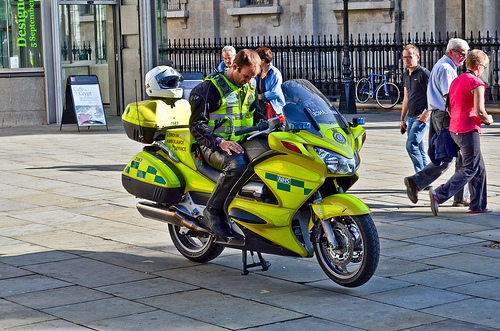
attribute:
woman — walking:
[427, 48, 495, 215]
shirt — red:
[446, 74, 487, 137]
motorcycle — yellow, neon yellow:
[121, 78, 379, 288]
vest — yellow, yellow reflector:
[202, 72, 256, 144]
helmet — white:
[144, 65, 183, 99]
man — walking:
[401, 43, 433, 191]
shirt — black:
[399, 65, 431, 118]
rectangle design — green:
[145, 164, 157, 174]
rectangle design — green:
[135, 168, 146, 178]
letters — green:
[14, 3, 39, 49]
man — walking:
[403, 36, 469, 207]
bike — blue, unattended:
[354, 64, 400, 109]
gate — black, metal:
[160, 31, 498, 103]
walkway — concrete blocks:
[1, 125, 500, 329]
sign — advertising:
[58, 74, 110, 133]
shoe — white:
[429, 188, 440, 215]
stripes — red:
[433, 192, 439, 203]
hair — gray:
[445, 37, 469, 55]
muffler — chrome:
[136, 201, 209, 232]